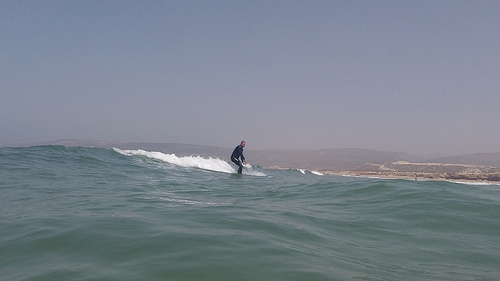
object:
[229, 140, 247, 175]
man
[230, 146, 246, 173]
wetsuit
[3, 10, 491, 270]
weather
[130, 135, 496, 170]
range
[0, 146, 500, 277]
ocean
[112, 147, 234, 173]
whitecap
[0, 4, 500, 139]
sky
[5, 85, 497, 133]
haze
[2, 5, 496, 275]
day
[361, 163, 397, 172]
paths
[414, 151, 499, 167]
mountains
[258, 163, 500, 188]
coast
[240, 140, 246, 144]
hair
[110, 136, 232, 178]
waves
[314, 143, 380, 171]
moutains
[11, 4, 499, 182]
distance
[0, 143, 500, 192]
shoreline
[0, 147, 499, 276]
waters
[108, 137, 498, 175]
land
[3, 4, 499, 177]
background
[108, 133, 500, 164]
tops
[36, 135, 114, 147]
hills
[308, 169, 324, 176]
splashes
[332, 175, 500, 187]
shore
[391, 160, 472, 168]
road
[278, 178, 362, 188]
strip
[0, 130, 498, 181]
landscape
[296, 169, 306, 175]
splash